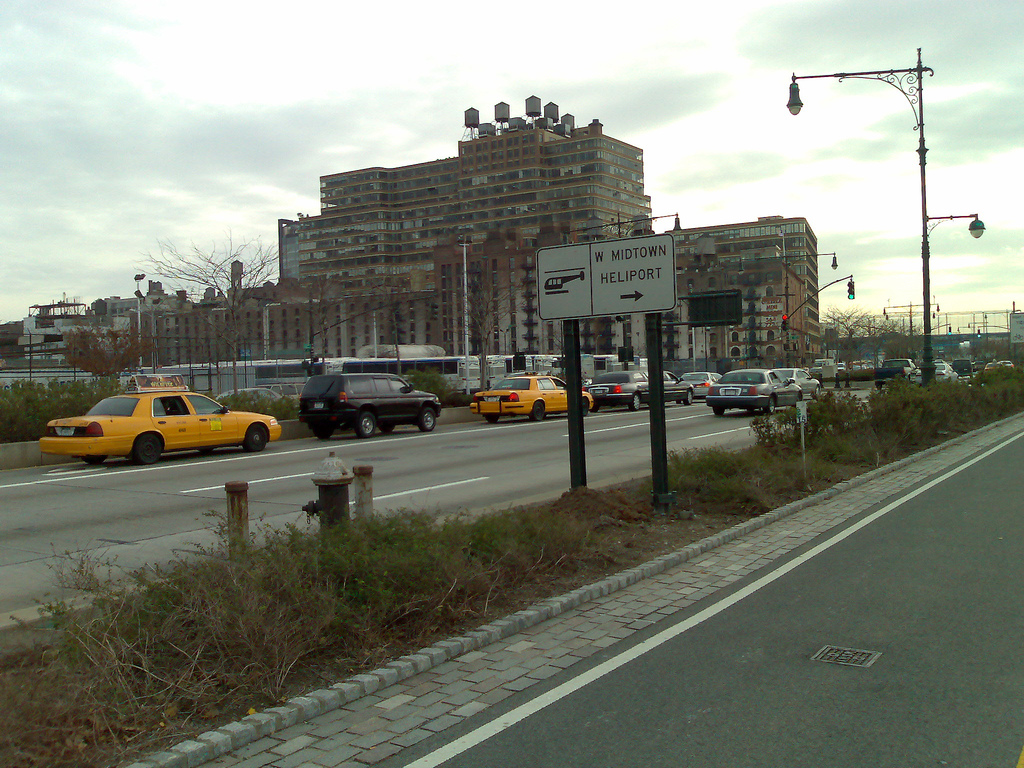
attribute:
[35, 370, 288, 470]
cab — yellow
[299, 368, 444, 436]
truck — black